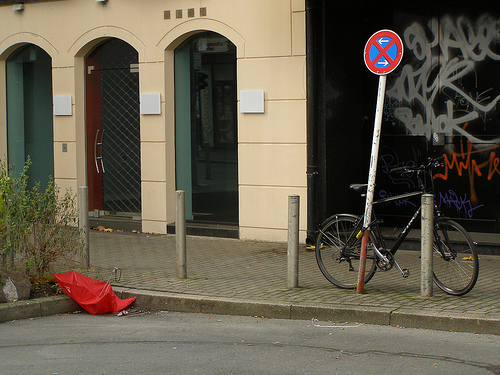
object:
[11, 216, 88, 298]
bush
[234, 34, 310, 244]
building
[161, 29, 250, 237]
doorway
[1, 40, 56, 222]
doorway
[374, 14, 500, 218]
graffiti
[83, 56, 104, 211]
red door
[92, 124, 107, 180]
silver handle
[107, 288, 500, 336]
curb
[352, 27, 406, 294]
pole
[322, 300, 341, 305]
brick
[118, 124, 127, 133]
mesh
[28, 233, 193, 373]
umbrella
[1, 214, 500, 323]
sidewalk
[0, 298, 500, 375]
ground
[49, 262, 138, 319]
garbage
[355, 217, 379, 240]
lock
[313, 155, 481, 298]
bicycle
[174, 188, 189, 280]
bollard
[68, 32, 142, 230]
door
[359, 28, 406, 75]
red sign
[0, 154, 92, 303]
bushes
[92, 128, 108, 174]
handle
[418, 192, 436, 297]
post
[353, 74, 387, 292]
pole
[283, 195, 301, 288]
poles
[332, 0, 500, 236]
building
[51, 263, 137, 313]
umbrella